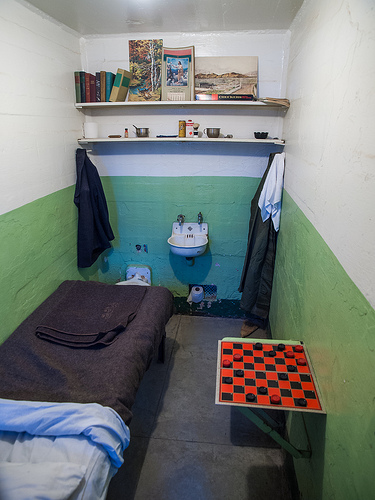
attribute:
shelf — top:
[75, 99, 293, 107]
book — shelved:
[111, 66, 132, 102]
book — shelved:
[105, 70, 110, 102]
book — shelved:
[85, 71, 97, 104]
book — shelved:
[74, 70, 82, 105]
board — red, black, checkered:
[218, 339, 321, 412]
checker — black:
[254, 341, 265, 351]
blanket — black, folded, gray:
[37, 278, 150, 351]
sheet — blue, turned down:
[0, 397, 135, 469]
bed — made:
[1, 278, 177, 497]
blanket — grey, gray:
[2, 277, 178, 421]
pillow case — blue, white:
[1, 463, 89, 499]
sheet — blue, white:
[1, 432, 119, 500]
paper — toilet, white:
[188, 285, 207, 306]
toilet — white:
[118, 263, 153, 286]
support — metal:
[234, 404, 311, 459]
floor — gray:
[111, 314, 298, 499]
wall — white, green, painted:
[269, 1, 374, 497]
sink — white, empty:
[169, 220, 211, 259]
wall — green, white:
[78, 28, 293, 302]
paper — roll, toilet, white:
[82, 119, 100, 142]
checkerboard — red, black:
[217, 336, 327, 414]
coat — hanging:
[237, 153, 276, 327]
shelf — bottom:
[79, 137, 288, 145]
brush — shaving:
[222, 131, 234, 141]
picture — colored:
[128, 38, 162, 102]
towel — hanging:
[258, 151, 284, 231]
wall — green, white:
[2, 0, 100, 343]